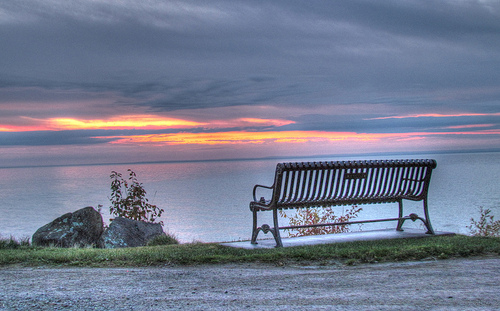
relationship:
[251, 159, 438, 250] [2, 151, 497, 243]
bench facing water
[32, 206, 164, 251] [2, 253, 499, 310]
rocks next to path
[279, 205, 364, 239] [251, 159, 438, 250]
shrub in front of bench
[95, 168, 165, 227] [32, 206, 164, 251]
leaves in front of rocks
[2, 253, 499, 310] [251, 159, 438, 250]
path behind bench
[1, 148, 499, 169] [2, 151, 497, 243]
horizon above water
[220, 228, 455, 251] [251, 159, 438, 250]
platform beneath bench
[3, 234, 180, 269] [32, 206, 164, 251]
grass next to rocks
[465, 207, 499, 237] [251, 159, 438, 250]
shrub on right of bench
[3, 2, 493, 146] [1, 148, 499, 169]
clouds above horizon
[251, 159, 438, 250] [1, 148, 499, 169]
bench facing horizon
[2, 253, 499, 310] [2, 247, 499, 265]
path has edge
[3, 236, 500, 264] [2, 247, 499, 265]
grass along edge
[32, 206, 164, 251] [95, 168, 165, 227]
rocks in front of leaves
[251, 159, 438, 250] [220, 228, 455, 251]
bench on platform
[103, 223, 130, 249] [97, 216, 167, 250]
lichen on rock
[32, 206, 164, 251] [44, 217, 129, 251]
rocks has lichen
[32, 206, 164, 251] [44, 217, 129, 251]
rocks have lichen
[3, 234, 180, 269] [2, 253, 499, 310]
grass beside path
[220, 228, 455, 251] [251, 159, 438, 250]
platform holding bench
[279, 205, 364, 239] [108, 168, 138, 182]
shrub has tops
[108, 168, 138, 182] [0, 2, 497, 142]
tops reaching for sky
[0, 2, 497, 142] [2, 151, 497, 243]
sky covering water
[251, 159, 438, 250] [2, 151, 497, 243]
bench over water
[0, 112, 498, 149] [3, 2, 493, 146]
sunset behind clouds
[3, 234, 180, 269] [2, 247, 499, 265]
grass on edge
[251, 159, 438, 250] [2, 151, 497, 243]
bench overlooking water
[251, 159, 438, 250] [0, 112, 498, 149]
bench overlooking sunset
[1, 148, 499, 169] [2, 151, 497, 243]
horizon over water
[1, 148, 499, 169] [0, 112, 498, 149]
horizon beneath sunset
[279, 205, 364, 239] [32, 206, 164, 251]
shrub next to rocks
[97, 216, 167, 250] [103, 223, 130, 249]
rock has lichen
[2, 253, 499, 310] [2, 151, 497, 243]
path over looking water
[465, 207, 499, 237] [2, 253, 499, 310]
shrub beside path